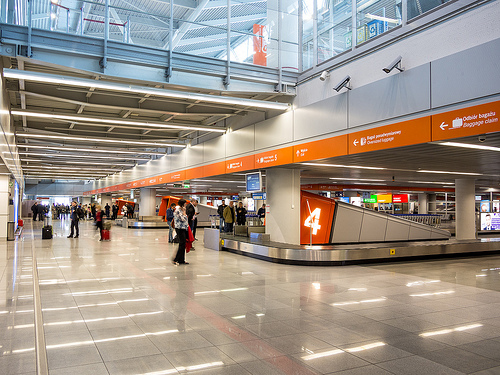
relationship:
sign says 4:
[301, 194, 336, 247] [304, 203, 325, 240]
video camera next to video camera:
[328, 73, 355, 94] [379, 52, 410, 78]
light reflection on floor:
[192, 282, 252, 300] [0, 208, 499, 372]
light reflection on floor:
[67, 281, 146, 300] [0, 208, 499, 372]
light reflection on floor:
[328, 288, 391, 317] [0, 208, 499, 372]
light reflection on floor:
[229, 307, 270, 326] [0, 208, 499, 372]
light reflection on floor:
[298, 334, 386, 367] [0, 208, 499, 372]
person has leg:
[67, 199, 82, 241] [67, 219, 76, 240]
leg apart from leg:
[67, 219, 76, 240] [73, 221, 80, 240]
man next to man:
[216, 198, 228, 228] [224, 201, 236, 233]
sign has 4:
[301, 194, 336, 247] [304, 203, 325, 240]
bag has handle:
[41, 225, 54, 242] [42, 215, 52, 228]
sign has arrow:
[429, 106, 499, 135] [438, 121, 451, 132]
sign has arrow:
[343, 115, 436, 152] [350, 136, 359, 150]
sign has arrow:
[252, 145, 294, 170] [256, 157, 262, 167]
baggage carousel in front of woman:
[214, 154, 499, 263] [170, 197, 193, 267]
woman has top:
[170, 197, 193, 267] [172, 207, 193, 232]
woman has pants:
[170, 197, 193, 267] [172, 227, 189, 266]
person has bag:
[93, 202, 105, 243] [99, 227, 110, 243]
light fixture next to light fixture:
[3, 62, 295, 114] [10, 105, 230, 137]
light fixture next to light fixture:
[13, 130, 188, 153] [13, 143, 171, 159]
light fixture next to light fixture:
[13, 143, 171, 159] [19, 154, 150, 170]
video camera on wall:
[328, 73, 355, 94] [294, 2, 500, 147]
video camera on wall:
[379, 52, 410, 78] [294, 2, 500, 147]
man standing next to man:
[216, 198, 228, 228] [224, 201, 236, 233]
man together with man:
[224, 201, 236, 233] [235, 201, 248, 226]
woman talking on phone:
[170, 197, 193, 267] [181, 205, 187, 211]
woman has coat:
[170, 197, 193, 267] [181, 225, 197, 253]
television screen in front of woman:
[244, 172, 265, 193] [170, 197, 193, 267]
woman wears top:
[170, 197, 193, 267] [172, 207, 193, 232]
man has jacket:
[216, 198, 228, 228] [222, 205, 237, 225]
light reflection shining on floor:
[298, 334, 386, 367] [0, 208, 499, 372]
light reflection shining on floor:
[328, 288, 391, 317] [0, 208, 499, 372]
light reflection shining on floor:
[229, 307, 270, 326] [0, 208, 499, 372]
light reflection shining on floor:
[192, 282, 252, 300] [0, 208, 499, 372]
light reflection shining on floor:
[67, 281, 146, 300] [0, 208, 499, 372]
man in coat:
[235, 201, 248, 226] [236, 206, 247, 223]